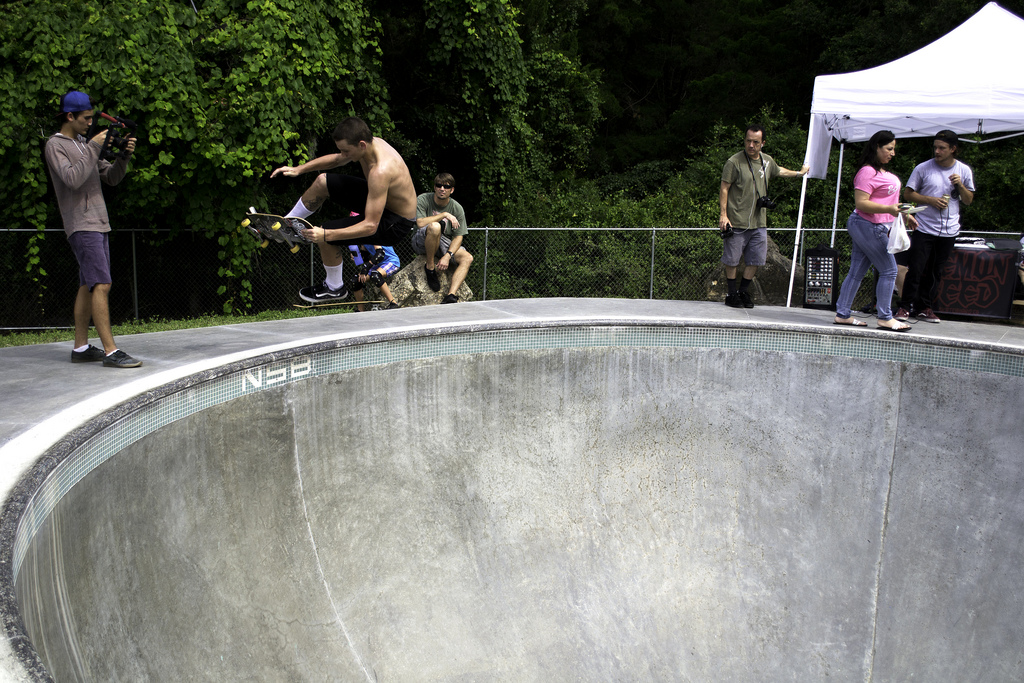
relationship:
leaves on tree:
[135, 87, 213, 172] [1, 0, 207, 310]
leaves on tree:
[221, 35, 304, 74] [121, 11, 355, 191]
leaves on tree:
[193, 59, 308, 133] [113, 5, 366, 198]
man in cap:
[43, 92, 142, 367] [53, 73, 114, 119]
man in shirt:
[57, 97, 137, 363] [50, 136, 130, 249]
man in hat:
[43, 92, 142, 367] [53, 66, 147, 140]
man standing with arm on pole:
[676, 103, 802, 330] [799, 211, 834, 227]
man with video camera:
[43, 92, 142, 367] [108, 203, 156, 225]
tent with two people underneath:
[747, 107, 1015, 136] [843, 203, 986, 236]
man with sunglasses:
[423, 215, 482, 295] [423, 170, 460, 207]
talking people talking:
[833, 130, 972, 332] [849, 203, 934, 251]